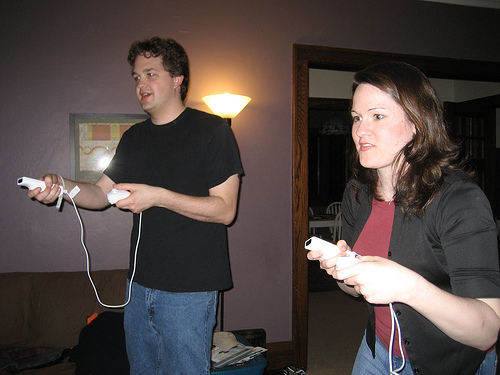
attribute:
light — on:
[202, 93, 252, 120]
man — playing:
[26, 39, 245, 374]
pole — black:
[221, 293, 225, 332]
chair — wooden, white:
[332, 209, 343, 248]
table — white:
[308, 212, 343, 243]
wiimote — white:
[17, 177, 65, 208]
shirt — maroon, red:
[352, 196, 409, 360]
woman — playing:
[306, 62, 496, 374]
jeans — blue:
[122, 276, 219, 374]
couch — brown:
[0, 272, 132, 374]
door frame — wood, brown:
[294, 44, 500, 373]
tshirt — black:
[105, 107, 234, 293]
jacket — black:
[337, 177, 499, 374]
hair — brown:
[351, 60, 475, 214]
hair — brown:
[128, 37, 190, 100]